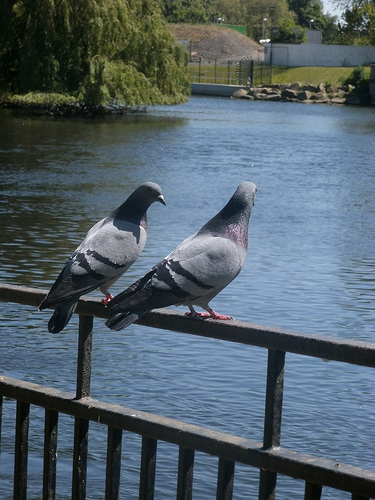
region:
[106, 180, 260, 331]
pigeon sitting on a metal railing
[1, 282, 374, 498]
black metal railing under pigeon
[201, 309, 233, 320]
red foot on railing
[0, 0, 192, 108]
large green tree next to the water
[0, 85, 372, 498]
water is calm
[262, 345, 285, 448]
black vertical bar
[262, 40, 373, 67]
white wall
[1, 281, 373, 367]
black horizontal rail under pigeons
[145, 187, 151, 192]
pigeon has a beady black eye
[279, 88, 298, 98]
rock next to rock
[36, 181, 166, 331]
pigeon to the left of a pigeon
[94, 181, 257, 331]
pigeon to the right of pigeon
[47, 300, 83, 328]
dark gray tail feather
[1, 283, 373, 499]
pigeon sitting on a metal railing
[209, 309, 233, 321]
pigeon has red feet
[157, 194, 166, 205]
pigeon has a pointy beak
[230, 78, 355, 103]
a large rock pile across the water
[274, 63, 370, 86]
grassy hill behind the rock pile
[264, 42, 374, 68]
white wall behind the hill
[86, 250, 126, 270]
pigeon has a black stripe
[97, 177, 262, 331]
gray pigeon standing on metal railing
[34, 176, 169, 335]
gray pigeon standing on metal railing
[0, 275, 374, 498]
gray metal railing next to lake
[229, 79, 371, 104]
light gray pile of large rocks next to lake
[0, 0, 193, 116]
green trees next to lake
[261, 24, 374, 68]
white building next to lake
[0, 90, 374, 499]
blue lake near building and rocks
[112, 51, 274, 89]
metal fence near lake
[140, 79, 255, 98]
short white wall next to lake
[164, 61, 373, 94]
small green grassy hill next to lake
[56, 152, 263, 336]
two pigeons on the railings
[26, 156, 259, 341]
two pigeons on the railings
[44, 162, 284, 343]
two pigeons on the railings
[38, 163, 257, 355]
two pigeons on the railings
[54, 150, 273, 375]
two pigeons on the railings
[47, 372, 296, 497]
the railings are black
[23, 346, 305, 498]
the railings are black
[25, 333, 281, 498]
the railings are black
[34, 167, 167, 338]
a pigeon sitting on a metal rail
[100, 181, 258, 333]
a pigeon sitting on a metal rail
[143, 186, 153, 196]
the eye of a pigeon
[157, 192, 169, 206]
the beak of a pigeon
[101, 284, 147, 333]
the tail of a pigeon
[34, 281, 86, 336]
the tail of a pigeon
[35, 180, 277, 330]
two pigeons on a metal rail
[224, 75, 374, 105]
a group of rocks near the water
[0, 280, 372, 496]
a rusted metal fence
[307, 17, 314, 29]
a lamp post in the background